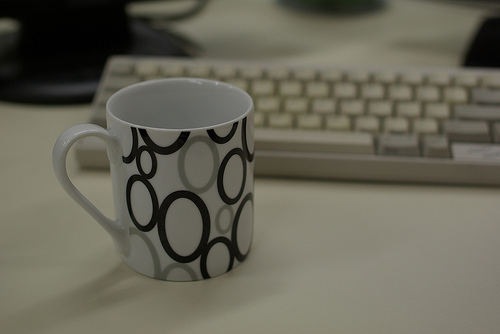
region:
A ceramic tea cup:
[40, 74, 312, 286]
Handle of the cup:
[48, 125, 122, 238]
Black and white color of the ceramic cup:
[36, 62, 297, 287]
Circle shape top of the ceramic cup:
[106, 71, 258, 128]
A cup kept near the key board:
[20, 70, 320, 292]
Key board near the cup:
[258, 45, 485, 140]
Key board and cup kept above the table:
[8, 52, 498, 332]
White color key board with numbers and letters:
[292, 66, 448, 152]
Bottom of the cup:
[127, 248, 289, 279]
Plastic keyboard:
[294, 65, 449, 132]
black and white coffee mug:
[51, 76, 260, 281]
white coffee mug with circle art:
[52, 76, 264, 279]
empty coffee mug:
[53, 76, 257, 282]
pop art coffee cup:
[50, 75, 288, 282]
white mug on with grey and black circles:
[50, 74, 278, 282]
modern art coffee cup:
[48, 78, 264, 281]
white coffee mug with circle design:
[51, 76, 258, 282]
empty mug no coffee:
[53, 76, 260, 283]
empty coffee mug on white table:
[54, 79, 259, 279]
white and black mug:
[104, 61, 242, 324]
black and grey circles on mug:
[122, 124, 266, 264]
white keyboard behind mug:
[165, 33, 490, 226]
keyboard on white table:
[221, 40, 436, 210]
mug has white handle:
[55, 100, 130, 233]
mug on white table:
[83, 77, 280, 327]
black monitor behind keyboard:
[18, 0, 153, 101]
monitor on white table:
[15, 0, 125, 106]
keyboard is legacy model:
[126, 60, 419, 227]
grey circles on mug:
[134, 132, 211, 209]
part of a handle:
[47, 157, 128, 283]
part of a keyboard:
[315, 117, 394, 237]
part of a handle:
[62, 160, 119, 229]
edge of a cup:
[168, 112, 254, 219]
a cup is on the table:
[50, 55, 278, 287]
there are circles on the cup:
[115, 105, 265, 270]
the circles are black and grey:
[112, 120, 250, 258]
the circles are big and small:
[169, 150, 250, 249]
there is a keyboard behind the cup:
[50, 35, 476, 180]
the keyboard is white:
[95, 33, 468, 185]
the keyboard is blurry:
[66, 43, 458, 181]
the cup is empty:
[29, 62, 274, 273]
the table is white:
[263, 188, 449, 319]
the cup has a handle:
[39, 112, 144, 257]